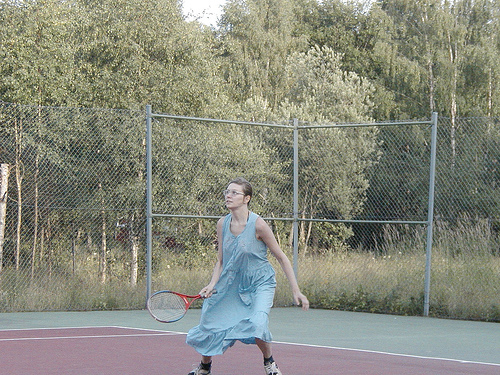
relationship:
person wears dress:
[187, 170, 321, 374] [181, 213, 280, 355]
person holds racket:
[187, 170, 321, 374] [146, 287, 217, 325]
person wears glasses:
[187, 170, 321, 374] [220, 189, 253, 199]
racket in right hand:
[146, 287, 217, 325] [198, 281, 215, 301]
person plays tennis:
[187, 170, 321, 374] [4, 276, 498, 371]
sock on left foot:
[264, 352, 280, 363] [256, 354, 292, 374]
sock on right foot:
[199, 357, 219, 367] [184, 358, 219, 374]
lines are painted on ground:
[1, 326, 184, 342] [7, 311, 499, 370]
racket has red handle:
[146, 287, 217, 325] [178, 292, 204, 308]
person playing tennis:
[187, 170, 321, 374] [4, 276, 498, 371]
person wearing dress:
[187, 170, 321, 374] [181, 213, 280, 355]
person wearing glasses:
[187, 170, 321, 374] [220, 189, 253, 199]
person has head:
[187, 170, 321, 374] [222, 175, 257, 209]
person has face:
[187, 170, 321, 374] [224, 186, 244, 204]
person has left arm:
[187, 170, 321, 374] [255, 217, 318, 308]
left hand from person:
[290, 288, 319, 310] [187, 170, 321, 374]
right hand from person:
[198, 281, 215, 301] [187, 170, 321, 374]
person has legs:
[187, 170, 321, 374] [191, 285, 284, 366]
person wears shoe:
[187, 170, 321, 374] [264, 362, 285, 374]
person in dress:
[187, 170, 321, 374] [181, 213, 280, 355]